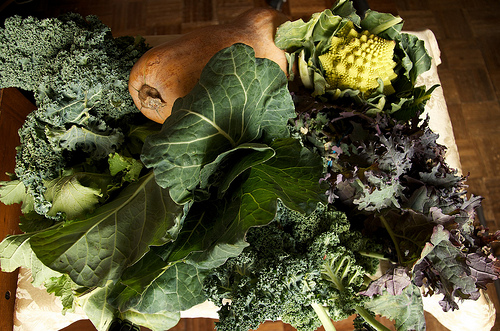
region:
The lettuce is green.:
[153, 95, 264, 198]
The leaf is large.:
[126, 43, 268, 202]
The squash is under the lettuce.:
[126, 7, 303, 118]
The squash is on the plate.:
[133, 10, 293, 131]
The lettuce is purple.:
[300, 106, 498, 321]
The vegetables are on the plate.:
[19, 18, 481, 320]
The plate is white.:
[182, 299, 222, 324]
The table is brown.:
[438, 9, 498, 189]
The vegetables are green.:
[1, 17, 132, 313]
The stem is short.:
[136, 82, 161, 113]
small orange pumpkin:
[131, 7, 322, 139]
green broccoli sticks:
[0, 11, 152, 201]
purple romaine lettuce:
[288, 120, 485, 327]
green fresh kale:
[15, 60, 327, 325]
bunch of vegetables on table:
[0, 10, 481, 317]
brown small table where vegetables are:
[10, 40, 478, 330]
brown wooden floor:
[0, 2, 497, 329]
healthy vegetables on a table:
[1, 11, 488, 318]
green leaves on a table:
[0, 12, 381, 329]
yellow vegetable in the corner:
[324, 27, 402, 101]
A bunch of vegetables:
[14, 24, 499, 294]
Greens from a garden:
[16, 15, 333, 330]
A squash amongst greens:
[122, 5, 293, 120]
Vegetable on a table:
[2, 8, 463, 328]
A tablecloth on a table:
[390, 5, 481, 328]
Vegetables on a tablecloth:
[5, 10, 490, 330]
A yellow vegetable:
[332, 25, 398, 86]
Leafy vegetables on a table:
[165, 96, 493, 289]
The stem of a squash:
[126, 75, 172, 112]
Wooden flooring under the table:
[428, 6, 498, 130]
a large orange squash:
[121, 2, 284, 113]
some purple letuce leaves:
[365, 180, 490, 320]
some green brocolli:
[15, 15, 135, 90]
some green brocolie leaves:
[25, 70, 130, 190]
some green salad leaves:
[175, 85, 305, 205]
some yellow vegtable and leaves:
[300, 15, 420, 95]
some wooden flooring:
[445, 20, 490, 120]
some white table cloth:
[425, 30, 470, 130]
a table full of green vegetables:
[23, 9, 496, 316]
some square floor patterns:
[460, 25, 490, 131]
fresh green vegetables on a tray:
[1, 5, 496, 327]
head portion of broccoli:
[210, 193, 378, 327]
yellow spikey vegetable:
[317, 20, 397, 91]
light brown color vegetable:
[128, 8, 299, 125]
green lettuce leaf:
[0, 43, 322, 327]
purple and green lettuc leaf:
[303, 99, 497, 307]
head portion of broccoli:
[0, 16, 147, 211]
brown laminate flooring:
[437, 2, 497, 227]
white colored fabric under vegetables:
[15, 255, 61, 329]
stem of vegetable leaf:
[319, 245, 386, 327]